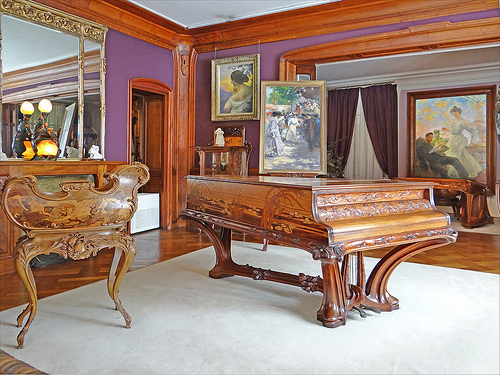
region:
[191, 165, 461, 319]
ornamental antique piano with curved legs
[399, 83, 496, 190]
framed painting on wall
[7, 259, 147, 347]
legs on antique furniture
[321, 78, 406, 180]
purple drapes on window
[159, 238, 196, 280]
white rug on wood floor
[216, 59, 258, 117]
painting of woman on wall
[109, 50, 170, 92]
purple wall around door frame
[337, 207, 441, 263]
closed cover on piano keys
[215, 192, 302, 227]
artwork on piano wood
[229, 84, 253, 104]
bare shoulder on painted woman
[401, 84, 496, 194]
painting on the wall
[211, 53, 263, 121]
painting of a woman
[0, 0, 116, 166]
mirror on the wall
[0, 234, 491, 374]
white carpet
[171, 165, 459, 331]
an ornate piano with engravings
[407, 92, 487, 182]
painting of man and woman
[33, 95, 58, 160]
a lit lamp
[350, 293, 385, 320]
piano foot pedals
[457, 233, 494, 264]
section of wood paneled floor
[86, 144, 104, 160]
small white statue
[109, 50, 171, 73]
purple painted wall in room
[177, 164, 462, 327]
antique wooden piano on rug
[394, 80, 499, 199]
framed art work on the wall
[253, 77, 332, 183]
framed art on an easel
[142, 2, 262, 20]
white ceiling of the room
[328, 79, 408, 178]
purple and cream colored curtains on window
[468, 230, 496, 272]
brown wooden floor in the room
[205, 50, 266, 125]
framed painting on the wall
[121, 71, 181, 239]
framed doorway in the room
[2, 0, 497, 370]
Antique furniture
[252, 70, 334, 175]
Colorful painting has brown frame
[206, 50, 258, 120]
Painting of a woman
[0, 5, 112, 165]
Mirror on wall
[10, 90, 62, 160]
Lights reflect in the mirror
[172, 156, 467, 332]
Old piano is brown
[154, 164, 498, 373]
Piano is on white carpet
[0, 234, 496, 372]
White carpet in center of room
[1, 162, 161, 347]
Chair has curved legs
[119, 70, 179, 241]
Door of room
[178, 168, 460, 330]
ornately carved grand piano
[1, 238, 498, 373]
large white area rug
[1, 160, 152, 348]
ornately carved musical instrument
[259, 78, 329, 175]
framed painting leaning against door frame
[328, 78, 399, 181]
burgundy colored tied-back curtains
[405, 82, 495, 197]
framed painting of a man and a woman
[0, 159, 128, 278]
fireplace with wooden mantle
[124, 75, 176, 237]
doorway to adjoining room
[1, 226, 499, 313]
wood tiled flooring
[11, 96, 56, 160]
reflection of two lamps in mirror